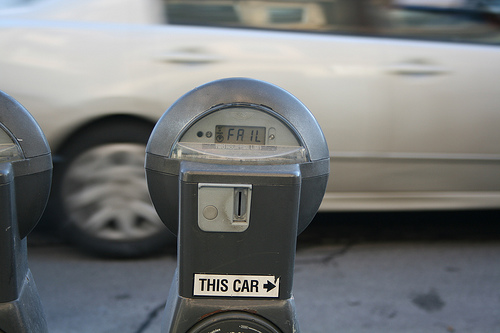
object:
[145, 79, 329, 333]
parking meter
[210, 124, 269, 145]
screen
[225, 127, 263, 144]
fail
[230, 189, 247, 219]
coin slot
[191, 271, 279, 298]
sticker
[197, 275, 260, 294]
this car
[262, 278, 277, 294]
arrow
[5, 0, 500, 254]
car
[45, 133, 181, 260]
tire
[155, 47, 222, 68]
handle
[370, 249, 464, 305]
road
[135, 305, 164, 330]
crack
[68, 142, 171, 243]
rim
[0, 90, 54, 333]
parking meter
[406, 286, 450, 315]
spots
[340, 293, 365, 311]
spot